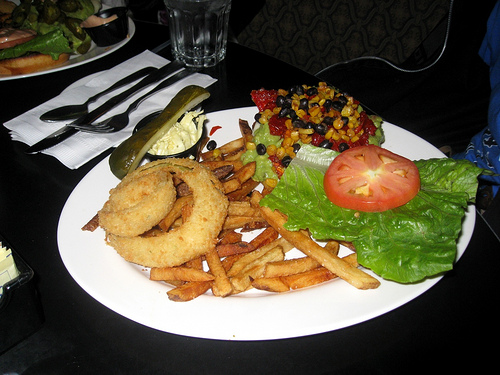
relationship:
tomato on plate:
[321, 148, 415, 210] [58, 98, 475, 338]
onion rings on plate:
[90, 146, 231, 275] [42, 92, 487, 350]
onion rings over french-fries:
[95, 155, 231, 269] [169, 148, 318, 309]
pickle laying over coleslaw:
[107, 84, 156, 174] [158, 102, 190, 160]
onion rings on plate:
[95, 155, 231, 269] [71, 175, 394, 353]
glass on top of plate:
[163, 6, 226, 84] [92, 102, 457, 331]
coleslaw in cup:
[151, 113, 191, 165] [149, 120, 196, 158]